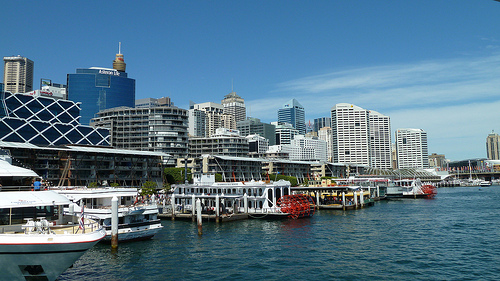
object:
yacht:
[0, 161, 107, 281]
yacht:
[149, 179, 292, 216]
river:
[309, 216, 494, 277]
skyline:
[4, 5, 497, 39]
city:
[0, 47, 497, 189]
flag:
[437, 163, 493, 174]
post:
[111, 196, 119, 253]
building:
[0, 40, 500, 251]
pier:
[296, 203, 365, 211]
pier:
[157, 206, 249, 222]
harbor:
[0, 180, 499, 281]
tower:
[113, 42, 126, 72]